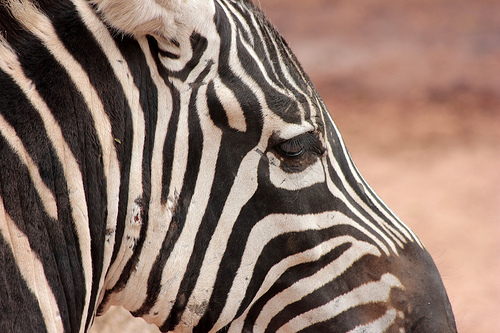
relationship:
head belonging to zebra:
[91, 1, 460, 331] [2, 1, 460, 331]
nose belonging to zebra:
[396, 242, 459, 331] [2, 1, 460, 331]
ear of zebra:
[95, 2, 218, 37] [2, 1, 460, 331]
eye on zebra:
[274, 133, 310, 157] [2, 1, 460, 331]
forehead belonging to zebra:
[212, 0, 332, 133] [2, 1, 460, 331]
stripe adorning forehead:
[212, 1, 265, 133] [212, 0, 332, 133]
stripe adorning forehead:
[220, 1, 253, 47] [212, 0, 332, 133]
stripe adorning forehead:
[238, 29, 291, 96] [212, 0, 332, 133]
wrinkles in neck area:
[71, 212, 128, 330] [25, 144, 160, 329]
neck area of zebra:
[25, 144, 160, 329] [2, 1, 460, 331]